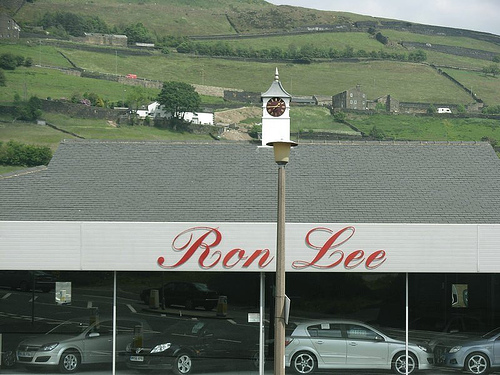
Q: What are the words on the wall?
A: Ron Lee.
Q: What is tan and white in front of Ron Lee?
A: Light pole.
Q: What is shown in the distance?
A: Countryside.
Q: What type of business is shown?
A: Car dealership.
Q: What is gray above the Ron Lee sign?
A: Roof.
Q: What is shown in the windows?
A: Cars.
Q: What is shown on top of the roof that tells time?
A: Clock.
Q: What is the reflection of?
A: Street.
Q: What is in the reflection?
A: Cars.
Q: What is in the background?
A: A hill.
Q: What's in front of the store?
A: A pole.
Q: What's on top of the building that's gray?
A: Roof.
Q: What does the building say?
A: Ron Lee.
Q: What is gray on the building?
A: The roof.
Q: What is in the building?
A: Cars.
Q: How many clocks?
A: One.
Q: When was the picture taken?
A: Daytime.